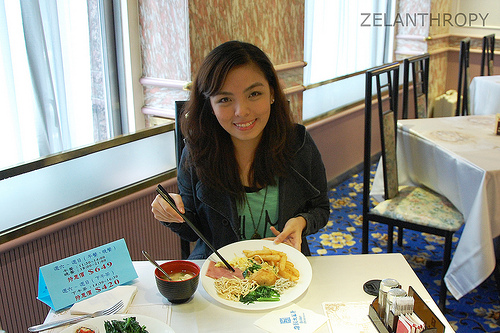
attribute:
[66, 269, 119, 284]
sign — blue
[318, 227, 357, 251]
flower — yellow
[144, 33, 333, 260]
girl — smiling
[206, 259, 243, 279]
food — Asian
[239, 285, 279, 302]
food — Asian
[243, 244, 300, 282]
food — Asian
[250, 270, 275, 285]
food — Asian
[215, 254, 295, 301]
food — Asian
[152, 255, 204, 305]
cup — small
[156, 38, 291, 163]
hair — long, brown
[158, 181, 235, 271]
chopsticks — black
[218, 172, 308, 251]
shirt — green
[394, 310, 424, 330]
packets — sugar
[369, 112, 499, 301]
tablecloth — white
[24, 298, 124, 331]
fork — stainless steel, silver